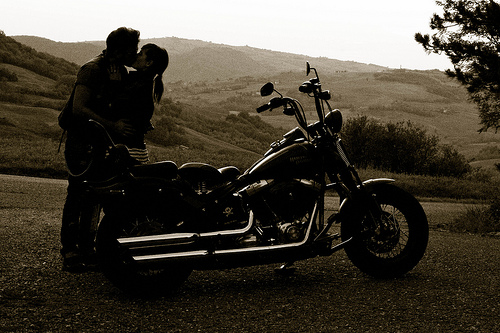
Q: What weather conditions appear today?
A: It is overcast.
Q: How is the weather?
A: It is overcast.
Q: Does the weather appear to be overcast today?
A: Yes, it is overcast.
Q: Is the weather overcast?
A: Yes, it is overcast.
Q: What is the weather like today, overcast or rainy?
A: It is overcast.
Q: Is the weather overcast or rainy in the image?
A: It is overcast.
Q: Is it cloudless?
A: No, it is overcast.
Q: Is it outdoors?
A: Yes, it is outdoors.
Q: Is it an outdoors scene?
A: Yes, it is outdoors.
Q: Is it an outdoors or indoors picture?
A: It is outdoors.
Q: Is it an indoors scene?
A: No, it is outdoors.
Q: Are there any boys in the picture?
A: No, there are no boys.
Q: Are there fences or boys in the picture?
A: No, there are no boys or fences.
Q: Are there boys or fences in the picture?
A: No, there are no boys or fences.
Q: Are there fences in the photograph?
A: No, there are no fences.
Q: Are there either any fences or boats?
A: No, there are no fences or boats.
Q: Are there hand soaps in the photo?
A: No, there are no hand soaps.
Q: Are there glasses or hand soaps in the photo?
A: No, there are no hand soaps or glasses.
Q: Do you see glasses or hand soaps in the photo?
A: No, there are no hand soaps or glasses.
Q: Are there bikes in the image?
A: Yes, there is a bike.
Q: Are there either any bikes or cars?
A: Yes, there is a bike.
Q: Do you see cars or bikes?
A: Yes, there is a bike.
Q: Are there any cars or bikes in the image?
A: Yes, there is a bike.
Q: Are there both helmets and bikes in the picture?
A: No, there is a bike but no helmets.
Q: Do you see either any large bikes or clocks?
A: Yes, there is a large bike.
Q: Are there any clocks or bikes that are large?
A: Yes, the bike is large.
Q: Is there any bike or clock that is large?
A: Yes, the bike is large.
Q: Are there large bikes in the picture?
A: Yes, there is a large bike.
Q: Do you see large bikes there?
A: Yes, there is a large bike.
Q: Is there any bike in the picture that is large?
A: Yes, there is a bike that is large.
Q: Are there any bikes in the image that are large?
A: Yes, there is a bike that is large.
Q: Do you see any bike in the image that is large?
A: Yes, there is a bike that is large.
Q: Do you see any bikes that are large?
A: Yes, there is a bike that is large.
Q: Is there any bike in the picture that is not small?
A: Yes, there is a large bike.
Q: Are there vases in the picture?
A: No, there are no vases.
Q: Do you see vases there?
A: No, there are no vases.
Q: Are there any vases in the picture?
A: No, there are no vases.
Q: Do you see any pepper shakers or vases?
A: No, there are no vases or pepper shakers.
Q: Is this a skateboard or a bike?
A: This is a bike.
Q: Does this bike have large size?
A: Yes, the bike is large.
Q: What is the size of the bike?
A: The bike is large.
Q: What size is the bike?
A: The bike is large.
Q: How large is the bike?
A: The bike is large.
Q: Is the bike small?
A: No, the bike is large.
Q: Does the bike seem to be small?
A: No, the bike is large.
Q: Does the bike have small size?
A: No, the bike is large.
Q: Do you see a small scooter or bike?
A: No, there is a bike but it is large.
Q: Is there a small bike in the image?
A: No, there is a bike but it is large.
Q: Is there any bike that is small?
A: No, there is a bike but it is large.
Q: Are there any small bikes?
A: No, there is a bike but it is large.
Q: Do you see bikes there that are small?
A: No, there is a bike but it is large.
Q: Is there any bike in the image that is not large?
A: No, there is a bike but it is large.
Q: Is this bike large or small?
A: The bike is large.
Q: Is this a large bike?
A: Yes, this is a large bike.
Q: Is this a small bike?
A: No, this is a large bike.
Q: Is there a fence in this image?
A: No, there are no fences.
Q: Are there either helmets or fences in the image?
A: No, there are no fences or helmets.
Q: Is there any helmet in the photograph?
A: No, there are no helmets.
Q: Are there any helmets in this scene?
A: No, there are no helmets.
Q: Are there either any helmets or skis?
A: No, there are no helmets or skis.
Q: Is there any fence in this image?
A: No, there are no fences.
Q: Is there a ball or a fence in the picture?
A: No, there are no fences or balls.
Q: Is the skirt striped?
A: Yes, the skirt is striped.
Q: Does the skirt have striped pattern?
A: Yes, the skirt is striped.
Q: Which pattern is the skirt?
A: The skirt is striped.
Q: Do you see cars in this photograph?
A: No, there are no cars.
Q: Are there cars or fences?
A: No, there are no cars or fences.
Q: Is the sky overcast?
A: Yes, the sky is overcast.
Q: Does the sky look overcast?
A: Yes, the sky is overcast.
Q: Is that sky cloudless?
A: No, the sky is overcast.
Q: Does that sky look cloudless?
A: No, the sky is overcast.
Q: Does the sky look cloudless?
A: No, the sky is overcast.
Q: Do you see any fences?
A: No, there are no fences.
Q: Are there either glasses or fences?
A: No, there are no fences or glasses.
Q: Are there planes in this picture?
A: No, there are no planes.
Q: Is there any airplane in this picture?
A: No, there are no airplanes.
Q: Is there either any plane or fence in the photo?
A: No, there are no airplanes or fences.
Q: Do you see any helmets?
A: No, there are no helmets.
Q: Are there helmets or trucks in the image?
A: No, there are no helmets or trucks.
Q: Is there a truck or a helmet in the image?
A: No, there are no helmets or trucks.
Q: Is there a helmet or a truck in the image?
A: No, there are no helmets or trucks.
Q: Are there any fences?
A: No, there are no fences.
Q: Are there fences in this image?
A: No, there are no fences.